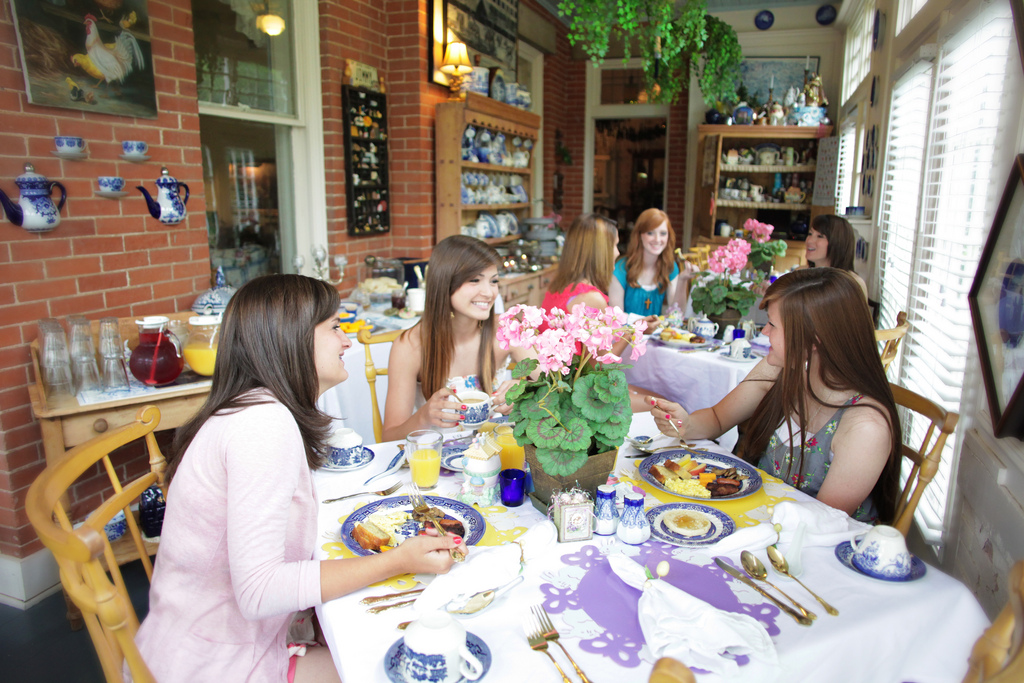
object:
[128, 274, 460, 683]
girl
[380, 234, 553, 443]
girl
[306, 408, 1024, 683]
table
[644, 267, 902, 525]
girl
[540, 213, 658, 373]
girl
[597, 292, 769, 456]
table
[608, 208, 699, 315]
girl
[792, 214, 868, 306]
girl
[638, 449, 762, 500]
plate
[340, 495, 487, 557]
plate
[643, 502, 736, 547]
plate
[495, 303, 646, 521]
plant